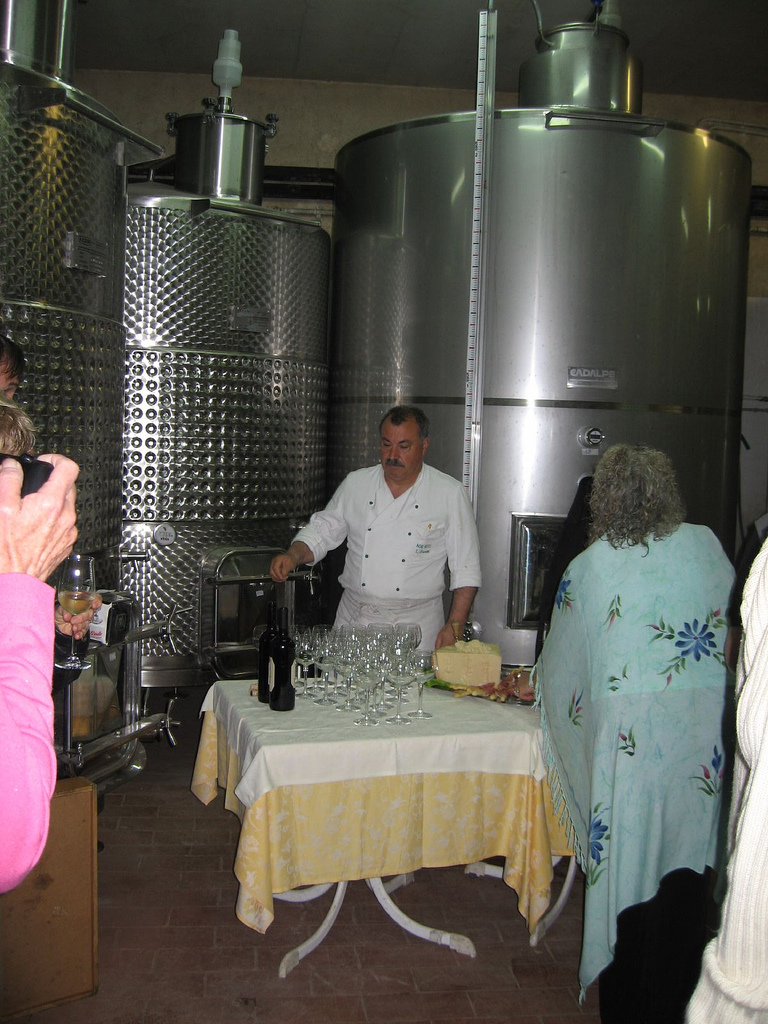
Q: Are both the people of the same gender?
A: No, they are both male and female.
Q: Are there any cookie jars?
A: No, there are no cookie jars.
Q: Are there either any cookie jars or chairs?
A: No, there are no cookie jars or chairs.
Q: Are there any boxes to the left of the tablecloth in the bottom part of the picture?
A: Yes, there is a box to the left of the tablecloth.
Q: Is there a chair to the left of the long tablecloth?
A: No, there is a box to the left of the tablecloth.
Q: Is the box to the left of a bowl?
A: No, the box is to the left of the tablecloth.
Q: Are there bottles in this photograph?
A: Yes, there is a bottle.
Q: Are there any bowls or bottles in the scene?
A: Yes, there is a bottle.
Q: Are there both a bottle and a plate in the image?
A: No, there is a bottle but no plates.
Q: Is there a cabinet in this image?
A: No, there are no cabinets.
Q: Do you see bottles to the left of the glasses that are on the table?
A: Yes, there is a bottle to the left of the glasses.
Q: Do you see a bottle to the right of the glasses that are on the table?
A: No, the bottle is to the left of the glasses.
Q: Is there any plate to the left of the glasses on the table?
A: No, there is a bottle to the left of the glasses.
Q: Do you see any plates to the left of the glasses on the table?
A: No, there is a bottle to the left of the glasses.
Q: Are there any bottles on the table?
A: Yes, there is a bottle on the table.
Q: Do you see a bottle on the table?
A: Yes, there is a bottle on the table.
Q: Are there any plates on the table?
A: No, there is a bottle on the table.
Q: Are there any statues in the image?
A: No, there are no statues.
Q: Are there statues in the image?
A: No, there are no statues.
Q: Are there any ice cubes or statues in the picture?
A: No, there are no statues or ice cubes.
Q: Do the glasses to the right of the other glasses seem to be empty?
A: Yes, the glasses are empty.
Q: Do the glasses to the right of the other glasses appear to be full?
A: No, the glasses are empty.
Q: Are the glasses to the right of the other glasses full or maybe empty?
A: The glasses are empty.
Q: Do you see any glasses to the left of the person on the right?
A: Yes, there are glasses to the left of the woman.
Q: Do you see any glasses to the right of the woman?
A: No, the glasses are to the left of the woman.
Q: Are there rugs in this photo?
A: No, there are no rugs.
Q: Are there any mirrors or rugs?
A: No, there are no rugs or mirrors.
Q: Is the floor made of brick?
A: Yes, the floor is made of brick.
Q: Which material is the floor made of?
A: The floor is made of brick.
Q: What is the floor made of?
A: The floor is made of brick.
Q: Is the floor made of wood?
A: No, the floor is made of brick.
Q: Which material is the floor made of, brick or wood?
A: The floor is made of brick.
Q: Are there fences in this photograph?
A: No, there are no fences.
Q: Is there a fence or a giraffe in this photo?
A: No, there are no fences or giraffes.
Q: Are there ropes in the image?
A: No, there are no ropes.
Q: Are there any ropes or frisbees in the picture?
A: No, there are no ropes or frisbees.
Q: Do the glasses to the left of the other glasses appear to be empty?
A: Yes, the glasses are empty.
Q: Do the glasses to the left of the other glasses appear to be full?
A: No, the glasses are empty.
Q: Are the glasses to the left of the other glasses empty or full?
A: The glasses are empty.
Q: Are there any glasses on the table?
A: Yes, there are glasses on the table.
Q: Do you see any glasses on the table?
A: Yes, there are glasses on the table.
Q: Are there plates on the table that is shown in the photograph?
A: No, there are glasses on the table.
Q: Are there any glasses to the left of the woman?
A: Yes, there are glasses to the left of the woman.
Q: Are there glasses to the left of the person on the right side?
A: Yes, there are glasses to the left of the woman.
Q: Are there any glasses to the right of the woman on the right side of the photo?
A: No, the glasses are to the left of the woman.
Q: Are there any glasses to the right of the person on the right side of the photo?
A: No, the glasses are to the left of the woman.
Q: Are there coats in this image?
A: Yes, there is a coat.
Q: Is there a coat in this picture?
A: Yes, there is a coat.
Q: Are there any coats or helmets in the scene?
A: Yes, there is a coat.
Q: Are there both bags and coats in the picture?
A: No, there is a coat but no bags.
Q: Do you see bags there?
A: No, there are no bags.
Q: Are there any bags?
A: No, there are no bags.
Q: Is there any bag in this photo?
A: No, there are no bags.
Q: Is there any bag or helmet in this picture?
A: No, there are no bags or helmets.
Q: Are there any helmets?
A: No, there are no helmets.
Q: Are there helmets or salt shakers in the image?
A: No, there are no helmets or salt shakers.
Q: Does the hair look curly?
A: Yes, the hair is curly.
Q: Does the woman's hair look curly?
A: Yes, the hair is curly.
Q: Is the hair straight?
A: No, the hair is curly.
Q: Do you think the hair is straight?
A: No, the hair is curly.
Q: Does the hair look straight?
A: No, the hair is curly.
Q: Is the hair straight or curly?
A: The hair is curly.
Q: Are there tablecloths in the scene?
A: Yes, there is a tablecloth.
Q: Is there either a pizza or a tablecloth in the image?
A: Yes, there is a tablecloth.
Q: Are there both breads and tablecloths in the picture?
A: No, there is a tablecloth but no breads.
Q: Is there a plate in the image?
A: No, there are no plates.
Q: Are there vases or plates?
A: No, there are no plates or vases.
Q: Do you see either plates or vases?
A: No, there are no plates or vases.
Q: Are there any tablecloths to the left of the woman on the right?
A: Yes, there is a tablecloth to the left of the woman.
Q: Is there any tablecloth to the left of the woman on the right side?
A: Yes, there is a tablecloth to the left of the woman.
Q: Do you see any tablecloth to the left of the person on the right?
A: Yes, there is a tablecloth to the left of the woman.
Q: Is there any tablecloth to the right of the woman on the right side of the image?
A: No, the tablecloth is to the left of the woman.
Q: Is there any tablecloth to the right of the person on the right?
A: No, the tablecloth is to the left of the woman.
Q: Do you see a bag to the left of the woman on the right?
A: No, there is a tablecloth to the left of the woman.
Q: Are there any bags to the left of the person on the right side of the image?
A: No, there is a tablecloth to the left of the woman.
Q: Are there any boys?
A: No, there are no boys.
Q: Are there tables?
A: Yes, there is a table.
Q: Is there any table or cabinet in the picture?
A: Yes, there is a table.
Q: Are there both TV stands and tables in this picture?
A: No, there is a table but no TV stands.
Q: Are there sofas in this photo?
A: No, there are no sofas.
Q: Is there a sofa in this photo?
A: No, there are no sofas.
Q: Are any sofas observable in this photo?
A: No, there are no sofas.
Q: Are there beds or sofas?
A: No, there are no sofas or beds.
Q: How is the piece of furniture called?
A: The piece of furniture is a table.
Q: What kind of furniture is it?
A: The piece of furniture is a table.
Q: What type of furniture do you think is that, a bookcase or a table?
A: This is a table.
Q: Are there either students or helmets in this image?
A: No, there are no helmets or students.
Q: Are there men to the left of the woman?
A: Yes, there is a man to the left of the woman.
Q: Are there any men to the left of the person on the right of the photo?
A: Yes, there is a man to the left of the woman.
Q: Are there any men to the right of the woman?
A: No, the man is to the left of the woman.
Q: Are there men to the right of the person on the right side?
A: No, the man is to the left of the woman.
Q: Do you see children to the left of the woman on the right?
A: No, there is a man to the left of the woman.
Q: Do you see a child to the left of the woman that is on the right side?
A: No, there is a man to the left of the woman.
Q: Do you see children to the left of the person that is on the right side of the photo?
A: No, there is a man to the left of the woman.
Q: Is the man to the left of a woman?
A: Yes, the man is to the left of a woman.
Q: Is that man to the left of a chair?
A: No, the man is to the left of a woman.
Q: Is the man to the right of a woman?
A: No, the man is to the left of a woman.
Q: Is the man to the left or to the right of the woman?
A: The man is to the left of the woman.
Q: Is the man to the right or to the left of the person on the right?
A: The man is to the left of the woman.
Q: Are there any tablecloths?
A: Yes, there is a tablecloth.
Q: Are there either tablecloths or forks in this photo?
A: Yes, there is a tablecloth.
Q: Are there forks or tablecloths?
A: Yes, there is a tablecloth.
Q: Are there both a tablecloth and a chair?
A: No, there is a tablecloth but no chairs.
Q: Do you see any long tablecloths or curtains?
A: Yes, there is a long tablecloth.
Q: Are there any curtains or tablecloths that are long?
A: Yes, the tablecloth is long.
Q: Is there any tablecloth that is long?
A: Yes, there is a long tablecloth.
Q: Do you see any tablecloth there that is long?
A: Yes, there is a tablecloth that is long.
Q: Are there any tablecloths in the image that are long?
A: Yes, there is a tablecloth that is long.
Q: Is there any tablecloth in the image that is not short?
A: Yes, there is a long tablecloth.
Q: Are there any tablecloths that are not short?
A: Yes, there is a long tablecloth.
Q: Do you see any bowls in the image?
A: No, there are no bowls.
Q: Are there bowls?
A: No, there are no bowls.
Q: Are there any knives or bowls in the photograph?
A: No, there are no bowls or knives.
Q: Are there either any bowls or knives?
A: No, there are no bowls or knives.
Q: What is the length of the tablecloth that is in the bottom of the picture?
A: The tablecloth is long.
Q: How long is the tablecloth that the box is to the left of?
A: The tablecloth is long.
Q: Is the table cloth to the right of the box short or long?
A: The tablecloth is long.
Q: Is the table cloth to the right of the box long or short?
A: The tablecloth is long.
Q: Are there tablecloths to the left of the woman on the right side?
A: Yes, there is a tablecloth to the left of the woman.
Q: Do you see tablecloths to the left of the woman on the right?
A: Yes, there is a tablecloth to the left of the woman.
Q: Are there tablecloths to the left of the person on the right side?
A: Yes, there is a tablecloth to the left of the woman.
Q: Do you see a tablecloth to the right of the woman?
A: No, the tablecloth is to the left of the woman.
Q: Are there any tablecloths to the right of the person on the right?
A: No, the tablecloth is to the left of the woman.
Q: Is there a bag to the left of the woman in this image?
A: No, there is a tablecloth to the left of the woman.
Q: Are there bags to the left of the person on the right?
A: No, there is a tablecloth to the left of the woman.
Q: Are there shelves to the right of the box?
A: No, there is a tablecloth to the right of the box.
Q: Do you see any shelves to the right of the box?
A: No, there is a tablecloth to the right of the box.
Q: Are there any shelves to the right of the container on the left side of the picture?
A: No, there is a tablecloth to the right of the box.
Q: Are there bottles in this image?
A: Yes, there is a bottle.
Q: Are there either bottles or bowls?
A: Yes, there is a bottle.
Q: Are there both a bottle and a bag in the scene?
A: No, there is a bottle but no bags.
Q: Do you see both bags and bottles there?
A: No, there is a bottle but no bags.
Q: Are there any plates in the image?
A: No, there are no plates.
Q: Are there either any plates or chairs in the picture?
A: No, there are no plates or chairs.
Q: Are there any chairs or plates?
A: No, there are no plates or chairs.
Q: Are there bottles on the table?
A: Yes, there is a bottle on the table.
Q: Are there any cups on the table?
A: No, there is a bottle on the table.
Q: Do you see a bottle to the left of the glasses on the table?
A: Yes, there is a bottle to the left of the glasses.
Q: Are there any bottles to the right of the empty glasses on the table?
A: No, the bottle is to the left of the glasses.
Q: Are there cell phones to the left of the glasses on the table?
A: No, there is a bottle to the left of the glasses.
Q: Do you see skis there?
A: No, there are no skis.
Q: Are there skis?
A: No, there are no skis.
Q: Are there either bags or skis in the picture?
A: No, there are no skis or bags.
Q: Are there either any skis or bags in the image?
A: No, there are no skis or bags.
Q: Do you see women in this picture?
A: Yes, there is a woman.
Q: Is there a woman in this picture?
A: Yes, there is a woman.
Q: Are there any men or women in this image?
A: Yes, there is a woman.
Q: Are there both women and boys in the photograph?
A: No, there is a woman but no boys.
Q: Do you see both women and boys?
A: No, there is a woman but no boys.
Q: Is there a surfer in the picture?
A: No, there are no surfers.